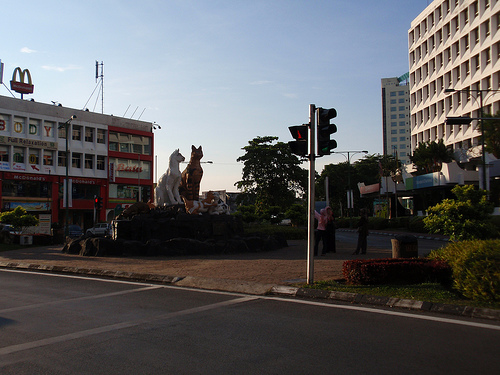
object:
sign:
[93, 58, 99, 79]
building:
[0, 59, 162, 248]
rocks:
[65, 238, 81, 257]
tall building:
[406, 0, 499, 219]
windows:
[396, 134, 408, 143]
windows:
[388, 98, 398, 104]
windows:
[55, 155, 67, 168]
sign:
[8, 80, 34, 95]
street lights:
[440, 87, 456, 94]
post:
[477, 90, 488, 193]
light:
[286, 123, 309, 141]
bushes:
[339, 254, 453, 285]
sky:
[0, 0, 433, 197]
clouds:
[0, 0, 441, 197]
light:
[318, 105, 338, 120]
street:
[0, 263, 499, 375]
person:
[312, 204, 331, 260]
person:
[350, 206, 371, 257]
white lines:
[0, 292, 259, 357]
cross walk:
[0, 284, 263, 356]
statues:
[153, 148, 187, 207]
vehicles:
[83, 221, 112, 237]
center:
[103, 144, 245, 241]